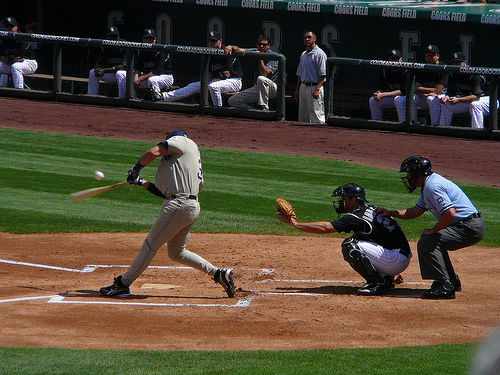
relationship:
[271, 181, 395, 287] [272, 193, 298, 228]
catcher wearing a mitt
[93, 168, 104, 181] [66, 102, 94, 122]
ball in air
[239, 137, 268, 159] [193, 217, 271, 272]
clay on ground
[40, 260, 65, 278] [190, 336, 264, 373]
lines are painted on field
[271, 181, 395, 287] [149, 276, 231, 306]
catcher behind home plate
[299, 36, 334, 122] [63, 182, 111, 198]
man swinging baseball bat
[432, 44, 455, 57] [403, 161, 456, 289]
helmets on umpire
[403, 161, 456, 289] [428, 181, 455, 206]
umpire wearing shirt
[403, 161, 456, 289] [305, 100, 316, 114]
umpire wearing pants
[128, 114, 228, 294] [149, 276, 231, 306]
batter at home plate